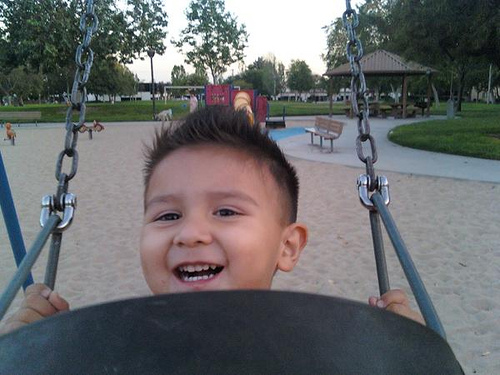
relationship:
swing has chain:
[15, 5, 464, 373] [344, 1, 398, 210]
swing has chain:
[15, 5, 464, 373] [56, 2, 99, 216]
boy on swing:
[24, 118, 418, 324] [15, 5, 464, 373]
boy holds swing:
[24, 118, 418, 324] [15, 5, 464, 373]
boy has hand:
[24, 118, 418, 324] [4, 275, 74, 343]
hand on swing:
[4, 275, 74, 343] [15, 5, 464, 373]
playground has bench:
[2, 106, 496, 374] [298, 109, 351, 154]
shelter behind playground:
[324, 49, 438, 119] [2, 106, 496, 374]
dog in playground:
[152, 103, 175, 124] [2, 106, 496, 374]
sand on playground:
[328, 187, 480, 281] [2, 106, 496, 374]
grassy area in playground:
[393, 118, 497, 167] [2, 106, 496, 374]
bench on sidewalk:
[298, 109, 351, 154] [278, 120, 500, 195]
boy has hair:
[24, 118, 418, 324] [133, 104, 303, 199]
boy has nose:
[24, 118, 418, 324] [175, 216, 212, 248]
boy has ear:
[24, 118, 418, 324] [275, 214, 308, 275]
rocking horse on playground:
[66, 113, 110, 146] [2, 106, 496, 374]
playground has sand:
[2, 106, 496, 374] [328, 187, 480, 281]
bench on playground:
[298, 109, 351, 154] [2, 106, 496, 374]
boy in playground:
[24, 118, 418, 324] [2, 106, 496, 374]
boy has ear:
[2, 106, 426, 331] [275, 214, 308, 275]